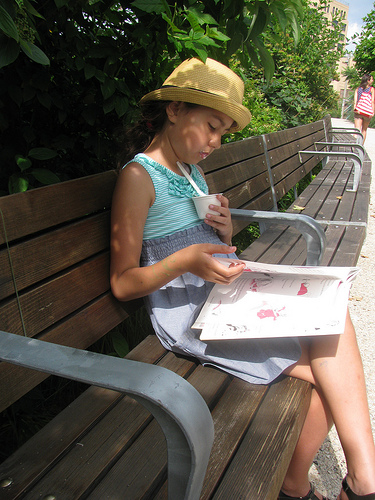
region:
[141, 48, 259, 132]
The girl is wearing a tan hat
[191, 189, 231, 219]
she is holding a white container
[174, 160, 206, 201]
there is a spoon in the white container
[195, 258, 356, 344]
The girl is reading the book in her lap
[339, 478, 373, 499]
she is wearing sandles that are blue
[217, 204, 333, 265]
there is a metal arm wrest next to the girl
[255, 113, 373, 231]
the benches are all attached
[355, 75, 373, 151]
a women walking down the sidewalk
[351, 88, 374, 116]
the woman has a red and white striped tote bag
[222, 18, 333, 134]
The trees behind the benches is green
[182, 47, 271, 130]
This girl is wearing a straw hat on her head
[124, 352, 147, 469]
There is a steel arm on this bench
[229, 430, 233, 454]
The bench is a dark brown color in the sun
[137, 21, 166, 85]
There are deep green leaves in the tree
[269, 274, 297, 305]
This girl is reading an illustrated children's book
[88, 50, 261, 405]
This is a rather nice day with partly sunny conditions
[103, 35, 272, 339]
This photo was taken in the city of Boston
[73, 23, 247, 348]
This photo was taken in the state of Massachusetts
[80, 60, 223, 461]
Jason Vince is the person who took the photo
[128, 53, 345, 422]
the girl is sitting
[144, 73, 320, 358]
the girl is reading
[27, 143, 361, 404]
the bench is long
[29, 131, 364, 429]
the bench is made of wood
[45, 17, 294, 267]
bushes behind the bench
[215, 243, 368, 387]
the book is open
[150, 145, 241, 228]
girl is holding a cup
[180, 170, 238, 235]
spoon in the cup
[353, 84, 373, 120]
the bag is stripes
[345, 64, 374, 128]
woman carrying a bag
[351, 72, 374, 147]
woman walking and holding a striped bag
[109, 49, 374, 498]
girl sitting on a bench in the shade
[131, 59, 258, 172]
girl wearing a hat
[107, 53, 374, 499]
girl wearing a blue top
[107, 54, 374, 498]
girl wearing a skirt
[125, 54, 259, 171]
girl with food on her mouth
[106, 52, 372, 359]
girl reading a magazine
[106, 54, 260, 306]
girl holding a cup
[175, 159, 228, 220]
white cup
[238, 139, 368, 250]
wooden bench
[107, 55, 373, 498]
A girl on a bench.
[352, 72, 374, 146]
A lady in the park.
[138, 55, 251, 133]
A brown straw hat.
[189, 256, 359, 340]
A book with pictures.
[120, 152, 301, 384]
A little girls sundress.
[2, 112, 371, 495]
A long park bench.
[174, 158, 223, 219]
A cup and spoon.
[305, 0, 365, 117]
A building in the background.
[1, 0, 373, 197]
Green plants in the park.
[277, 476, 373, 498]
Part of some sandals.